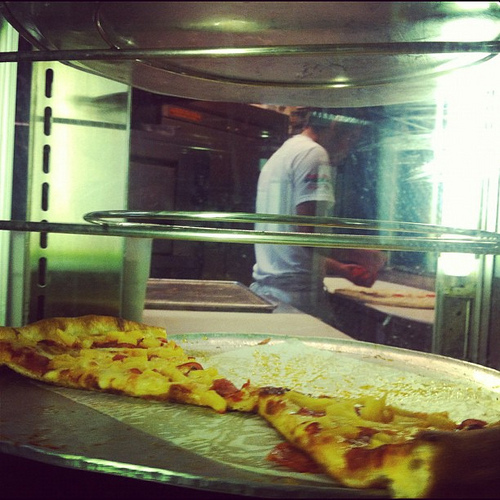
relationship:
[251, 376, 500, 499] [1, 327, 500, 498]
pizza on tray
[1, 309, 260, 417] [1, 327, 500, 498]
pizza on tray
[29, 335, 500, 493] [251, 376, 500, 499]
paper underneath pizza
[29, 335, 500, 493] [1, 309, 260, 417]
paper underneath pizza